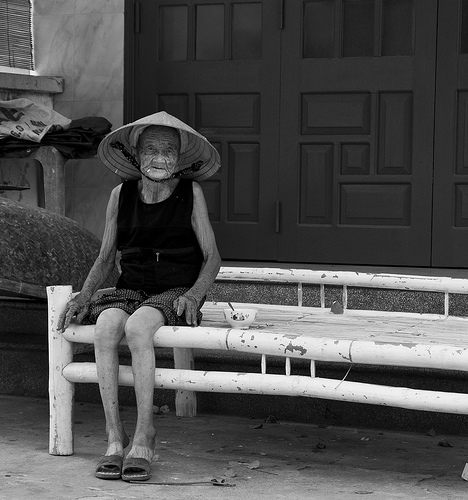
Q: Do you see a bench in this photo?
A: Yes, there is a bench.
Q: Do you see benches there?
A: Yes, there is a bench.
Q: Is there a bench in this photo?
A: Yes, there is a bench.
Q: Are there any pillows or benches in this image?
A: Yes, there is a bench.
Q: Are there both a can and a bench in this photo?
A: No, there is a bench but no cans.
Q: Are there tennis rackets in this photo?
A: No, there are no tennis rackets.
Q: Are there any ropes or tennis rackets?
A: No, there are no tennis rackets or ropes.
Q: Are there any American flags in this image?
A: No, there are no American flags.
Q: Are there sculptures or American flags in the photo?
A: No, there are no American flags or sculptures.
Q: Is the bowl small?
A: Yes, the bowl is small.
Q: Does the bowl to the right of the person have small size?
A: Yes, the bowl is small.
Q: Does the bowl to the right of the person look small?
A: Yes, the bowl is small.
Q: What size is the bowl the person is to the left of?
A: The bowl is small.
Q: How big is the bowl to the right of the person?
A: The bowl is small.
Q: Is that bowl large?
A: No, the bowl is small.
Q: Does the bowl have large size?
A: No, the bowl is small.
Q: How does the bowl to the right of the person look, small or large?
A: The bowl is small.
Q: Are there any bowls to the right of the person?
A: Yes, there is a bowl to the right of the person.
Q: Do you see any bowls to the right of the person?
A: Yes, there is a bowl to the right of the person.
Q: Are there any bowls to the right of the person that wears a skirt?
A: Yes, there is a bowl to the right of the person.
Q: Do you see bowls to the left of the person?
A: No, the bowl is to the right of the person.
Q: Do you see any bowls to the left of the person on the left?
A: No, the bowl is to the right of the person.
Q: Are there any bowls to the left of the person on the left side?
A: No, the bowl is to the right of the person.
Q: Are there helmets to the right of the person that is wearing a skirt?
A: No, there is a bowl to the right of the person.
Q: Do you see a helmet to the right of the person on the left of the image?
A: No, there is a bowl to the right of the person.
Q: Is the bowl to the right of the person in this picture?
A: Yes, the bowl is to the right of the person.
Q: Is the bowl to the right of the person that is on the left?
A: Yes, the bowl is to the right of the person.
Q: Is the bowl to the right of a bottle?
A: No, the bowl is to the right of the person.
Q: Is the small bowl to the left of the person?
A: No, the bowl is to the right of the person.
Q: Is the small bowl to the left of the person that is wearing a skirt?
A: No, the bowl is to the right of the person.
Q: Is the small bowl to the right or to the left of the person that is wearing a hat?
A: The bowl is to the right of the person.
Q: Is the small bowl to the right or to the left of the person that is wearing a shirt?
A: The bowl is to the right of the person.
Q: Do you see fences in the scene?
A: No, there are no fences.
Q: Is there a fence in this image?
A: No, there are no fences.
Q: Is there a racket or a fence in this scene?
A: No, there are no fences or rackets.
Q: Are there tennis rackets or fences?
A: No, there are no fences or tennis rackets.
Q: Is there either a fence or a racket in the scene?
A: No, there are no fences or rackets.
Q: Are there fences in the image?
A: No, there are no fences.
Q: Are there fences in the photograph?
A: No, there are no fences.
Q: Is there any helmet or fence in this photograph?
A: No, there are no fences or helmets.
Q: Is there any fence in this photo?
A: No, there are no fences.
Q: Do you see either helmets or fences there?
A: No, there are no fences or helmets.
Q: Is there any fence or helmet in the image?
A: No, there are no fences or helmets.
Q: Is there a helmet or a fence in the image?
A: No, there are no fences or helmets.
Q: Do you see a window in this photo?
A: Yes, there is a window.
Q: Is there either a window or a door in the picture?
A: Yes, there is a window.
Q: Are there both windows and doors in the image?
A: Yes, there are both a window and a door.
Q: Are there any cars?
A: No, there are no cars.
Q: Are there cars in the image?
A: No, there are no cars.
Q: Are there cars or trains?
A: No, there are no cars or trains.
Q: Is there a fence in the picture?
A: No, there are no fences.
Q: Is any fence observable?
A: No, there are no fences.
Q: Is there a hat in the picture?
A: Yes, there is a hat.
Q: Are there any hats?
A: Yes, there is a hat.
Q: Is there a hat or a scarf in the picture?
A: Yes, there is a hat.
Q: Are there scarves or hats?
A: Yes, there is a hat.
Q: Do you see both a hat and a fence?
A: No, there is a hat but no fences.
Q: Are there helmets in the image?
A: No, there are no helmets.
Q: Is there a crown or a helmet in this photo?
A: No, there are no helmets or crowns.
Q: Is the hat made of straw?
A: Yes, the hat is made of straw.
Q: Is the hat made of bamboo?
A: No, the hat is made of straw.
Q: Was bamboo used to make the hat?
A: No, the hat is made of straw.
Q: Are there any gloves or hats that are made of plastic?
A: No, there is a hat but it is made of straw.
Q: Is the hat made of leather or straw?
A: The hat is made of straw.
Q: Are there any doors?
A: Yes, there is a door.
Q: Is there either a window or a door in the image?
A: Yes, there is a door.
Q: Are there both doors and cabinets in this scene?
A: No, there is a door but no cabinets.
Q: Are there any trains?
A: No, there are no trains.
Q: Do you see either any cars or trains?
A: No, there are no trains or cars.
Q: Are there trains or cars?
A: No, there are no trains or cars.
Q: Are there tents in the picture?
A: No, there are no tents.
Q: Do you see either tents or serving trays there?
A: No, there are no tents or serving trays.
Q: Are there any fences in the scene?
A: No, there are no fences.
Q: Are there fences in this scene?
A: No, there are no fences.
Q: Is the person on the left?
A: Yes, the person is on the left of the image.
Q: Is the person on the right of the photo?
A: No, the person is on the left of the image.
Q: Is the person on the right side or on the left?
A: The person is on the left of the image.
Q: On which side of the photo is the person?
A: The person is on the left of the image.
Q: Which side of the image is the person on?
A: The person is on the left of the image.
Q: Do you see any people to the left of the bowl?
A: Yes, there is a person to the left of the bowl.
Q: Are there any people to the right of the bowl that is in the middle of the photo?
A: No, the person is to the left of the bowl.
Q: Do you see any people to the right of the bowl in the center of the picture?
A: No, the person is to the left of the bowl.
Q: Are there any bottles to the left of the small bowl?
A: No, there is a person to the left of the bowl.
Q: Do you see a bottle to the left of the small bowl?
A: No, there is a person to the left of the bowl.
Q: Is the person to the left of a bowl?
A: Yes, the person is to the left of a bowl.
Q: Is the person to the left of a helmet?
A: No, the person is to the left of a bowl.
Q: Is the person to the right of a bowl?
A: No, the person is to the left of a bowl.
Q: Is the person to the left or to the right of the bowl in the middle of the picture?
A: The person is to the left of the bowl.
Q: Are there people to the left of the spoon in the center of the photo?
A: Yes, there is a person to the left of the spoon.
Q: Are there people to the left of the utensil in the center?
A: Yes, there is a person to the left of the spoon.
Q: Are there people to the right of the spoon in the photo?
A: No, the person is to the left of the spoon.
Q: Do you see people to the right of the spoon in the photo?
A: No, the person is to the left of the spoon.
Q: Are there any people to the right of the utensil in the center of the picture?
A: No, the person is to the left of the spoon.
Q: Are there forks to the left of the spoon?
A: No, there is a person to the left of the spoon.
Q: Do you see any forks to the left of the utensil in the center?
A: No, there is a person to the left of the spoon.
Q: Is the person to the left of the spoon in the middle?
A: Yes, the person is to the left of the spoon.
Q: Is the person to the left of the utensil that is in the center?
A: Yes, the person is to the left of the spoon.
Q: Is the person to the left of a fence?
A: No, the person is to the left of the spoon.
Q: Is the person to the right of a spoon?
A: No, the person is to the left of a spoon.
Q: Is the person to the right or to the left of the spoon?
A: The person is to the left of the spoon.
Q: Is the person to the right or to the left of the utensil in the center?
A: The person is to the left of the spoon.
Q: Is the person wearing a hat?
A: Yes, the person is wearing a hat.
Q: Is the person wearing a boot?
A: No, the person is wearing a hat.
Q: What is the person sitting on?
A: The person is sitting on the bench.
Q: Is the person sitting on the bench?
A: Yes, the person is sitting on the bench.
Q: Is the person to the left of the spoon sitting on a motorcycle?
A: No, the person is sitting on the bench.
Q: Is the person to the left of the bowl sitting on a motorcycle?
A: No, the person is sitting on the bench.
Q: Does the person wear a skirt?
A: Yes, the person wears a skirt.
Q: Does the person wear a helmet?
A: No, the person wears a skirt.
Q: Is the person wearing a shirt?
A: Yes, the person is wearing a shirt.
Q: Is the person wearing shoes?
A: Yes, the person is wearing shoes.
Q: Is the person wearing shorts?
A: No, the person is wearing shoes.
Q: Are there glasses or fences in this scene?
A: No, there are no fences or glasses.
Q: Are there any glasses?
A: No, there are no glasses.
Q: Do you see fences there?
A: No, there are no fences.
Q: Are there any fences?
A: No, there are no fences.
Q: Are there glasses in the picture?
A: No, there are no glasses.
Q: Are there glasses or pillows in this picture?
A: No, there are no glasses or pillows.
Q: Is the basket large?
A: Yes, the basket is large.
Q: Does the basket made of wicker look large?
A: Yes, the basket is large.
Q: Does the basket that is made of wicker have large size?
A: Yes, the basket is large.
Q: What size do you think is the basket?
A: The basket is large.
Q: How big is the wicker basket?
A: The basket is large.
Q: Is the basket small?
A: No, the basket is large.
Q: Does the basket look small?
A: No, the basket is large.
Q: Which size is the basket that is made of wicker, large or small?
A: The basket is large.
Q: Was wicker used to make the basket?
A: Yes, the basket is made of wicker.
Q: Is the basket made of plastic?
A: No, the basket is made of wicker.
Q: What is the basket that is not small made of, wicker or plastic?
A: The basket is made of wicker.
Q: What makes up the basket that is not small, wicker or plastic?
A: The basket is made of wicker.